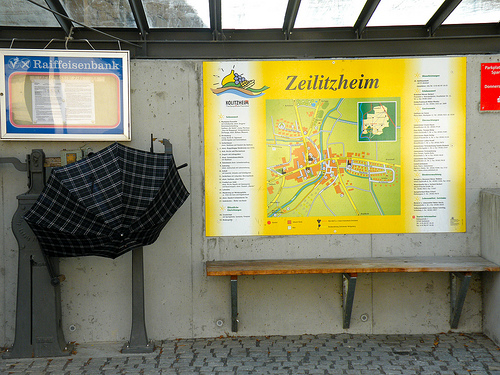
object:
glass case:
[0, 47, 136, 144]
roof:
[5, 0, 497, 43]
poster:
[201, 57, 471, 238]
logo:
[208, 68, 269, 105]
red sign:
[480, 61, 498, 112]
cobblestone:
[177, 352, 194, 359]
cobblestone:
[258, 338, 274, 348]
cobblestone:
[437, 355, 460, 365]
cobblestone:
[325, 356, 341, 361]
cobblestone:
[320, 360, 335, 366]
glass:
[292, 0, 368, 29]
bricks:
[230, 348, 247, 357]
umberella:
[25, 140, 192, 262]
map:
[202, 60, 473, 235]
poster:
[4, 55, 126, 137]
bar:
[449, 270, 476, 331]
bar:
[337, 268, 357, 330]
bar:
[227, 277, 239, 331]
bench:
[204, 254, 499, 331]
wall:
[4, 50, 496, 332]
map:
[259, 90, 411, 232]